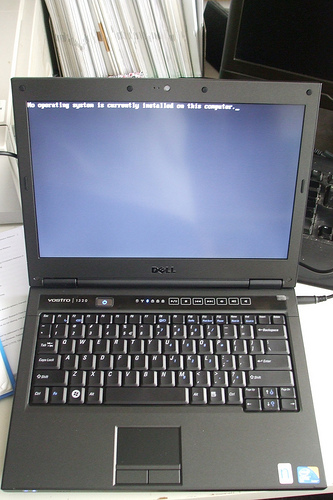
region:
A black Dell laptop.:
[138, 260, 189, 280]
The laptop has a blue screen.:
[61, 126, 274, 250]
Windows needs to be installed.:
[26, 101, 251, 125]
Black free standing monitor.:
[190, 7, 323, 73]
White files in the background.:
[53, 3, 189, 71]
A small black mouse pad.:
[95, 419, 187, 486]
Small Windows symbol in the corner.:
[292, 454, 322, 494]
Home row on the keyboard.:
[60, 350, 213, 363]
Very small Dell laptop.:
[5, 297, 322, 494]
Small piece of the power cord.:
[299, 285, 330, 310]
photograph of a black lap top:
[15, 71, 330, 492]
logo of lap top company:
[145, 259, 186, 279]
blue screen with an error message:
[19, 91, 252, 126]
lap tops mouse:
[111, 417, 203, 485]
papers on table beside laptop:
[5, 224, 55, 401]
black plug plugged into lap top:
[285, 283, 331, 304]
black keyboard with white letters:
[21, 307, 293, 412]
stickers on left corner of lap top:
[273, 458, 321, 487]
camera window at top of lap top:
[151, 82, 183, 96]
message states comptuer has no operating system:
[22, 89, 245, 118]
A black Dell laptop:
[0, 75, 328, 489]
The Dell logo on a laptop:
[152, 266, 175, 273]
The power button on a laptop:
[95, 297, 114, 306]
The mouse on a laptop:
[116, 425, 181, 484]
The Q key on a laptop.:
[58, 336, 76, 354]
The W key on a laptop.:
[76, 338, 91, 353]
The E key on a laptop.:
[93, 338, 108, 354]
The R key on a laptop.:
[110, 337, 127, 352]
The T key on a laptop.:
[129, 339, 143, 355]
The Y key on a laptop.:
[146, 338, 160, 351]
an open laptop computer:
[0, 74, 326, 488]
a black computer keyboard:
[29, 311, 297, 410]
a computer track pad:
[114, 425, 181, 484]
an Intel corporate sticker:
[297, 465, 319, 482]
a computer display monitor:
[27, 100, 307, 274]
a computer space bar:
[101, 386, 190, 405]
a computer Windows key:
[67, 385, 84, 404]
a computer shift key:
[246, 369, 293, 385]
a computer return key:
[252, 355, 291, 371]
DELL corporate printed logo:
[147, 263, 177, 275]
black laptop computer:
[10, 73, 320, 493]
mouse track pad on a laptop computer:
[115, 426, 183, 485]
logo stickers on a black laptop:
[271, 455, 320, 484]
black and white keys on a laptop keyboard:
[37, 308, 297, 412]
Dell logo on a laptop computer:
[142, 261, 187, 276]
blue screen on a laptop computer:
[30, 95, 298, 267]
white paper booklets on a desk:
[50, 1, 203, 75]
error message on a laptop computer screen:
[19, 89, 251, 121]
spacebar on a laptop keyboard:
[104, 386, 187, 405]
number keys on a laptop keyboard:
[52, 322, 217, 340]